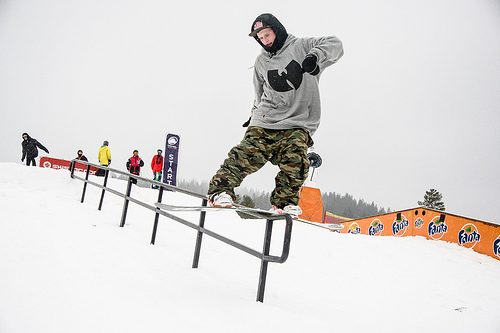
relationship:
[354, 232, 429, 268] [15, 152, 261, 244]
snow on a hill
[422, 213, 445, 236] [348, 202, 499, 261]
logo on a fence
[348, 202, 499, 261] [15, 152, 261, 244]
fence on a hill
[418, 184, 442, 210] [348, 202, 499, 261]
tree behind a fence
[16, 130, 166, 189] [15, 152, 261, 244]
people on a hill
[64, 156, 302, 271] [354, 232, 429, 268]
rail in snow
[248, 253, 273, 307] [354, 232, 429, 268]
pole in snow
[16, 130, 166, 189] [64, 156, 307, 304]
people behind rail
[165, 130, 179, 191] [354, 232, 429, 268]
sign in snow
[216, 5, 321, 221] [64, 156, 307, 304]
boy on rail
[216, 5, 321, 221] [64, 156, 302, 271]
man on rail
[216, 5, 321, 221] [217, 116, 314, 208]
man wearing camoflauge pants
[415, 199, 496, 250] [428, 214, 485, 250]
divider advertising fanta soda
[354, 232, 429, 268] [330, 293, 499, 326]
snow on ground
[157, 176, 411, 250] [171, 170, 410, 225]
mountain with trees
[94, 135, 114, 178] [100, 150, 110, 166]
person in yellow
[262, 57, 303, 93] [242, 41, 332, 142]
emblem on hoodie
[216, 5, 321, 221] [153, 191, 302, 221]
guy on a snowboard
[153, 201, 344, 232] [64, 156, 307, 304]
snowboard on rail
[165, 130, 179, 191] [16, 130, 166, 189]
sign near people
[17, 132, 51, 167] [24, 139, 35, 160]
people in all black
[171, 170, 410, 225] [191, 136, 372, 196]
trees in background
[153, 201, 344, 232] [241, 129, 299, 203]
snowboard wearing fatigue pants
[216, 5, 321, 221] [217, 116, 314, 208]
man has camoflauge pants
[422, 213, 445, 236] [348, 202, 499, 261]
logo on fence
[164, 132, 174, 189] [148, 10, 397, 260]
starting point for performance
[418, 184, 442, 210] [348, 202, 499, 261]
tree behind fence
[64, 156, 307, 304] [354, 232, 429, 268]
rail sticking out snow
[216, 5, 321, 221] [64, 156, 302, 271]
man skateboarding on rail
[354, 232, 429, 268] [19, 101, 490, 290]
snow at event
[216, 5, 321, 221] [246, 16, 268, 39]
man wearing a hat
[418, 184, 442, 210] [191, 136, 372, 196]
tree in background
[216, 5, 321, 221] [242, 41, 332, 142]
man wearing a sweatshirt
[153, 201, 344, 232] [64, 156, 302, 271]
snowboard riding rail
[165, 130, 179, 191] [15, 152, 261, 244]
sign at top of hill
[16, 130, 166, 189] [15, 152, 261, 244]
snowboarder waiting on hill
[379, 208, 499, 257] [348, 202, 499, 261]
advertisement on fence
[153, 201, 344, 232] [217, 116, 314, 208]
snowboard wearing camoflauge pants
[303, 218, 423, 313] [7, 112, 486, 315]
winter at ski resort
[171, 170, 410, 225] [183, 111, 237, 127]
trees in distance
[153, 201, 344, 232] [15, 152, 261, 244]
snowboard ready to descend hill